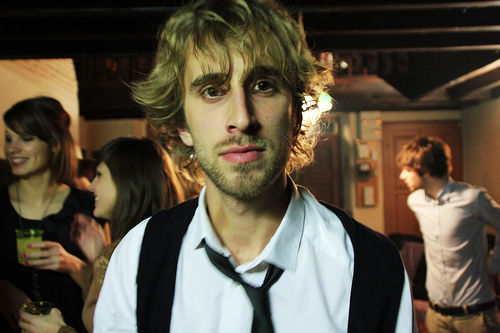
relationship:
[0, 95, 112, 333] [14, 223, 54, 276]
girl holding drink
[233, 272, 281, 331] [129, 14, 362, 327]
black tie man man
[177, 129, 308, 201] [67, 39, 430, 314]
beard on man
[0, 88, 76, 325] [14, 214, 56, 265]
girl holding drink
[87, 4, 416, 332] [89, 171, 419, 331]
man wears shirt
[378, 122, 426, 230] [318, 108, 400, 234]
wood door on back wall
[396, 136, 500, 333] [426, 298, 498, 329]
boy on man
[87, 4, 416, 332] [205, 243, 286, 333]
man wearing black tie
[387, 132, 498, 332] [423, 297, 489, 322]
boy wearing belt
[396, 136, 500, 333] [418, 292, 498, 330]
boy wearing khaki pants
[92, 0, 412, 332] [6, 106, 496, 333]
man in room